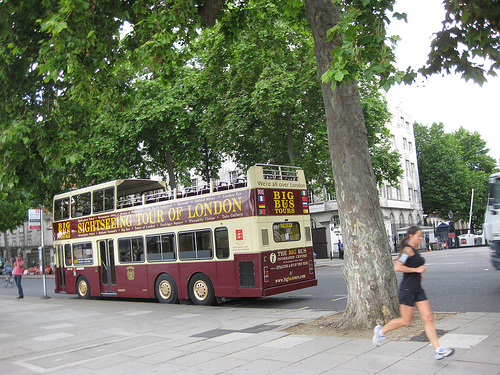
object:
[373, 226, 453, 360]
girl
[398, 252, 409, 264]
band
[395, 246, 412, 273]
arm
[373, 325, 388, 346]
shoes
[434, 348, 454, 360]
feet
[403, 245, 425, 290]
top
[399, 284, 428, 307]
shorts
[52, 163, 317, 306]
bus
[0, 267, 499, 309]
road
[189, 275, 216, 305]
wheel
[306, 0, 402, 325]
trunk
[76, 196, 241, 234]
writing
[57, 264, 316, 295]
bottom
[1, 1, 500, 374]
london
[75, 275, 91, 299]
wheel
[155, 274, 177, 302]
wheels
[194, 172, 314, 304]
back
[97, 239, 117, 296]
door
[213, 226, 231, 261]
windows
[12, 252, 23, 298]
woman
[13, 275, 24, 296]
jeans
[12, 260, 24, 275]
shirt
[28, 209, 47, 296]
signpost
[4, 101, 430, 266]
architecture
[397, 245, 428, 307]
clothing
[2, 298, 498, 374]
sidewalk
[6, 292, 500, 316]
curbside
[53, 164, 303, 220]
deck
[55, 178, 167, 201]
roof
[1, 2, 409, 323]
trees